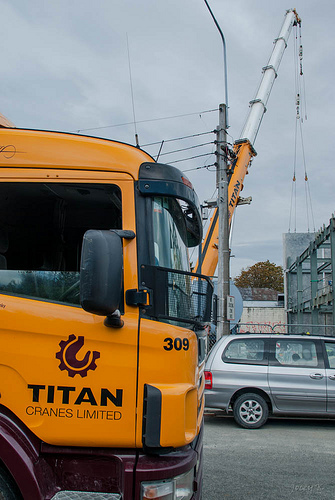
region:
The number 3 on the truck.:
[160, 335, 172, 351]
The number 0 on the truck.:
[172, 336, 184, 352]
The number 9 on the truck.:
[183, 337, 188, 352]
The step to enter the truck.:
[54, 470, 113, 498]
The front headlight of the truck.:
[141, 471, 196, 497]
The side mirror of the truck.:
[84, 223, 123, 320]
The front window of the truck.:
[156, 196, 201, 324]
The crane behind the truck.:
[185, 4, 320, 278]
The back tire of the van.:
[234, 393, 263, 426]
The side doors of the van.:
[267, 337, 334, 409]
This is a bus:
[11, 269, 212, 453]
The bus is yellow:
[75, 312, 175, 407]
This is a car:
[210, 331, 288, 409]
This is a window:
[231, 344, 280, 373]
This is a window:
[236, 385, 289, 441]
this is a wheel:
[243, 404, 260, 422]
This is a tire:
[238, 401, 243, 404]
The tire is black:
[231, 394, 239, 401]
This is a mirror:
[67, 223, 122, 341]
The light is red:
[200, 368, 219, 384]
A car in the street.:
[204, 331, 334, 428]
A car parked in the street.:
[203, 333, 334, 428]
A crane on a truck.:
[190, 7, 317, 280]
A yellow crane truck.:
[0, 111, 317, 498]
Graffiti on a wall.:
[239, 321, 286, 334]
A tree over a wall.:
[232, 259, 284, 301]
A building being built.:
[282, 212, 332, 336]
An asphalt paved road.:
[202, 416, 334, 498]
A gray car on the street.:
[204, 331, 334, 428]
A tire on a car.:
[232, 392, 269, 430]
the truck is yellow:
[0, 132, 202, 496]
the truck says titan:
[27, 384, 122, 406]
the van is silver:
[202, 334, 333, 420]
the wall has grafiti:
[238, 320, 285, 331]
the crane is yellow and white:
[195, 10, 297, 278]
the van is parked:
[204, 335, 334, 423]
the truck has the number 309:
[163, 338, 187, 351]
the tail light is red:
[203, 371, 212, 388]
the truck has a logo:
[55, 334, 99, 378]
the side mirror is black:
[84, 227, 132, 329]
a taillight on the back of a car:
[201, 362, 215, 390]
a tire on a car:
[238, 389, 264, 427]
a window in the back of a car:
[221, 332, 274, 371]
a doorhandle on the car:
[308, 368, 327, 384]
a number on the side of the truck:
[157, 331, 198, 361]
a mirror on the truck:
[77, 225, 130, 333]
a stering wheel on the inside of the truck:
[58, 270, 85, 309]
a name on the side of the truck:
[16, 367, 130, 429]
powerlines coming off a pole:
[155, 121, 220, 174]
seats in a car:
[295, 338, 316, 366]